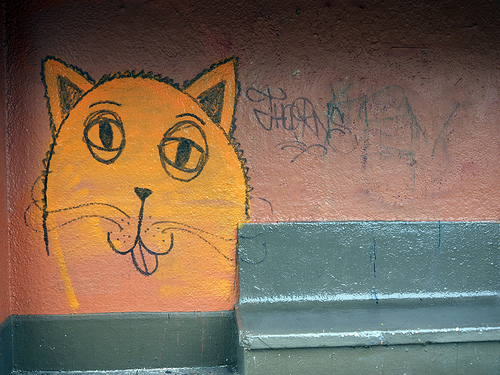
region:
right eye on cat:
[153, 129, 210, 178]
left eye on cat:
[77, 112, 127, 162]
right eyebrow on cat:
[171, 104, 210, 126]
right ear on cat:
[200, 49, 245, 109]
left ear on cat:
[34, 52, 82, 99]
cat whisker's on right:
[207, 222, 247, 267]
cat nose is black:
[128, 181, 158, 208]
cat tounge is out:
[131, 246, 161, 278]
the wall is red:
[16, 16, 371, 356]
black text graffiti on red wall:
[242, 78, 394, 178]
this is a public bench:
[233, 182, 495, 335]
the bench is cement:
[237, 199, 484, 365]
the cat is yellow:
[19, 25, 236, 327]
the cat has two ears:
[28, 37, 280, 297]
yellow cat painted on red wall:
[20, 18, 327, 353]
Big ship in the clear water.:
[140, 265, 204, 289]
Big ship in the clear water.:
[160, 361, 188, 373]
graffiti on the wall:
[40, 45, 118, 149]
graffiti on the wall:
[179, 39, 249, 123]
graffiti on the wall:
[76, 102, 146, 192]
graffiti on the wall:
[150, 92, 225, 207]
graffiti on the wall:
[87, 162, 191, 302]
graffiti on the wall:
[225, 52, 275, 132]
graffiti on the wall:
[320, 101, 377, 162]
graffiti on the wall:
[397, 91, 467, 171]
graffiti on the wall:
[9, 158, 53, 225]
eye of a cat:
[77, 83, 152, 168]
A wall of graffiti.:
[3, 3, 492, 299]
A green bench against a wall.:
[235, 224, 496, 368]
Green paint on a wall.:
[2, 308, 242, 372]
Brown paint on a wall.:
[2, 3, 494, 307]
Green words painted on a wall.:
[242, 78, 469, 168]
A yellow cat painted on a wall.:
[20, 51, 241, 308]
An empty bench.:
[233, 223, 494, 370]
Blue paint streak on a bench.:
[370, 223, 380, 307]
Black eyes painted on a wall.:
[80, 98, 210, 180]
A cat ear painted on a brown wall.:
[35, 53, 95, 133]